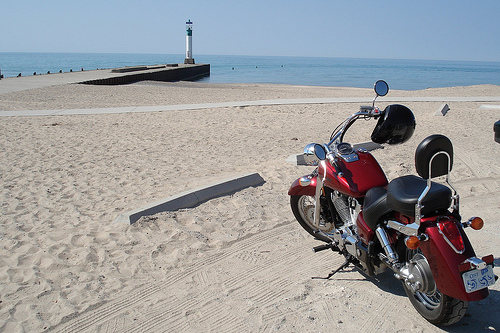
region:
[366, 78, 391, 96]
mirror on the motorcycle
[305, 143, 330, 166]
mirror on the motorcycle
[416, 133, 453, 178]
back rest on motorcycle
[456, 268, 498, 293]
license plate on motorcycle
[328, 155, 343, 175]
handle bar on motorcycle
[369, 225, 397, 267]
brake on motorcycle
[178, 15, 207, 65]
light house on the beach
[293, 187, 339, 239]
tire wheel on motorcycle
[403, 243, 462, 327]
tire wheel on motorcycle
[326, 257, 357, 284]
kick stand on motorcycle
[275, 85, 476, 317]
the motorbike is parked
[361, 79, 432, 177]
the helmet is black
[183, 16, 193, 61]
Small lighthouse on a pier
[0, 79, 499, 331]
Empty sandy beach in daytime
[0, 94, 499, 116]
Cement sidewalk running through the sand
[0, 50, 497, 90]
Blue ocean water in the landscape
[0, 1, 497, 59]
Clear blue daytime skies in distance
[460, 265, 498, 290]
License plate on motorcycle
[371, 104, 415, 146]
Black motorcycle helmet hanging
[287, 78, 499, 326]
Motorcycle parked in the sand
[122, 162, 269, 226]
Parking curb marker in the sand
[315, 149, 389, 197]
Red paint trim on motorcycle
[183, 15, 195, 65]
Lighthouse at the end of the pier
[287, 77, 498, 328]
Red motorcycle parked off the beach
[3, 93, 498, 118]
Sidewalk through the sandy beach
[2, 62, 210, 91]
Pier leading into the ocean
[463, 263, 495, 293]
White license plate at the rear of the motorcycle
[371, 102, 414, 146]
Black motorcycle helmet hanging from handlebar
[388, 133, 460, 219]
Motorcycle's passanger seat at rear of the cycle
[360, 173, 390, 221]
Driver seat in middle of the motorcycle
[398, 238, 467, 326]
Rear wheel of the motorcycle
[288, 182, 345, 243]
Front wheel of the red motorcycle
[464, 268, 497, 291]
white license plate on back of motorcycle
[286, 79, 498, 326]
red and black motorcycle on beach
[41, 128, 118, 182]
sand on beach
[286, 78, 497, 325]
motorcycle parked near water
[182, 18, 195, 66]
lighthouse near water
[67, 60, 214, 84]
wooden dock on beach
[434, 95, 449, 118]
concrete block on beach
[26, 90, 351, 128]
walkway on beach in sand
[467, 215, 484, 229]
light on back of motocycle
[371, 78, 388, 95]
silver mirror on motorcycle